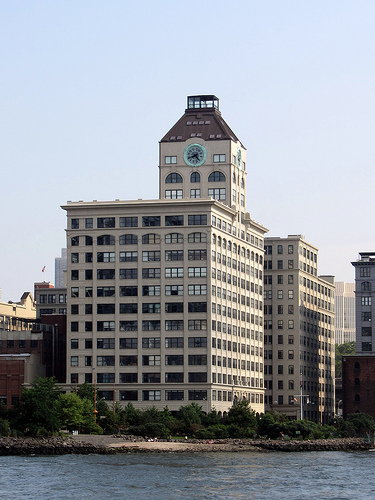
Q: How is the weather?
A: Clear.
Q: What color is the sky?
A: Blue.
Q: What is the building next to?
A: Water.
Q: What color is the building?
A: White.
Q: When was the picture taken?
A: Daytime.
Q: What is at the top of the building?
A: A clock.